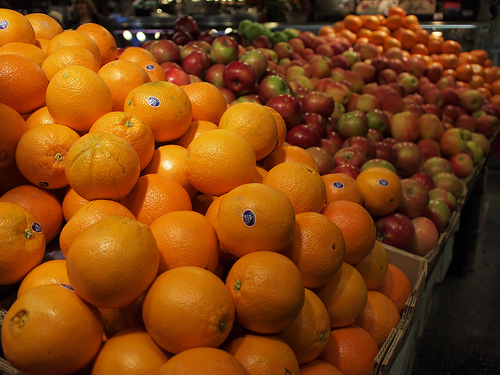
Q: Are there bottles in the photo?
A: No, there are no bottles.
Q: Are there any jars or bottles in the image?
A: No, there are no bottles or jars.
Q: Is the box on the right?
A: Yes, the box is on the right of the image.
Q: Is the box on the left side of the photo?
A: No, the box is on the right of the image.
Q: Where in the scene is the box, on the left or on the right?
A: The box is on the right of the image.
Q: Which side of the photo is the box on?
A: The box is on the right of the image.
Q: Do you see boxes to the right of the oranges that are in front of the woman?
A: Yes, there is a box to the right of the oranges.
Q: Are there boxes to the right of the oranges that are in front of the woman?
A: Yes, there is a box to the right of the oranges.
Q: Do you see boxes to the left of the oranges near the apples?
A: No, the box is to the right of the oranges.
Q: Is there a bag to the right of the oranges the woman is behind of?
A: No, there is a box to the right of the oranges.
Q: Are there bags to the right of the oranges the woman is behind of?
A: No, there is a box to the right of the oranges.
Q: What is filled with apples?
A: The box is filled with apples.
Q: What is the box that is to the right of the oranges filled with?
A: The box is filled with apples.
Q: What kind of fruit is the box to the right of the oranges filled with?
A: The box is filled with apples.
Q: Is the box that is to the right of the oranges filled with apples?
A: Yes, the box is filled with apples.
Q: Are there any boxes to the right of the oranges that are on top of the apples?
A: Yes, there is a box to the right of the oranges.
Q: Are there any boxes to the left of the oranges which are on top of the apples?
A: No, the box is to the right of the oranges.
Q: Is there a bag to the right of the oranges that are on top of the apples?
A: No, there is a box to the right of the oranges.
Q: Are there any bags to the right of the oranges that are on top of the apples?
A: No, there is a box to the right of the oranges.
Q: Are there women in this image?
A: Yes, there is a woman.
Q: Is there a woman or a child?
A: Yes, there is a woman.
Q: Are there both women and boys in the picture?
A: No, there is a woman but no boys.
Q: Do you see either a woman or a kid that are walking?
A: Yes, the woman is walking.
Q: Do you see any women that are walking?
A: Yes, there is a woman that is walking.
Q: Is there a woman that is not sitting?
A: Yes, there is a woman that is walking.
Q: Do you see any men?
A: No, there are no men.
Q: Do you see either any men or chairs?
A: No, there are no men or chairs.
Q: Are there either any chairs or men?
A: No, there are no men or chairs.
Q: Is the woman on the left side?
A: Yes, the woman is on the left of the image.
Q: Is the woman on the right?
A: No, the woman is on the left of the image.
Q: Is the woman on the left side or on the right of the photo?
A: The woman is on the left of the image.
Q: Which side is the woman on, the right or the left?
A: The woman is on the left of the image.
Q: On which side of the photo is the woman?
A: The woman is on the left of the image.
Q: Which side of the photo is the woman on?
A: The woman is on the left of the image.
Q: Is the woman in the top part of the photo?
A: Yes, the woman is in the top of the image.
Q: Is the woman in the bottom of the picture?
A: No, the woman is in the top of the image.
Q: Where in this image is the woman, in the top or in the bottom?
A: The woman is in the top of the image.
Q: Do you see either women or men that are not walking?
A: No, there is a woman but she is walking.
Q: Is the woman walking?
A: Yes, the woman is walking.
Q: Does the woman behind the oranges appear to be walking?
A: Yes, the woman is walking.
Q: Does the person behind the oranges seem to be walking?
A: Yes, the woman is walking.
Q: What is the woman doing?
A: The woman is walking.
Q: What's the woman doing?
A: The woman is walking.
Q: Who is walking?
A: The woman is walking.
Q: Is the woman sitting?
A: No, the woman is walking.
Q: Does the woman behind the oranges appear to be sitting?
A: No, the woman is walking.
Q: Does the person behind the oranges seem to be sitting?
A: No, the woman is walking.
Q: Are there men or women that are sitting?
A: No, there is a woman but she is walking.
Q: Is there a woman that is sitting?
A: No, there is a woman but she is walking.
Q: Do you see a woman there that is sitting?
A: No, there is a woman but she is walking.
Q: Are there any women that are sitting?
A: No, there is a woman but she is walking.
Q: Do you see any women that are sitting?
A: No, there is a woman but she is walking.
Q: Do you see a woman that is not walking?
A: No, there is a woman but she is walking.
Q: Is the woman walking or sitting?
A: The woman is walking.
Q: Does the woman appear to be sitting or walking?
A: The woman is walking.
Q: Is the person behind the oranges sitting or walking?
A: The woman is walking.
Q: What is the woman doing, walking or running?
A: The woman is walking.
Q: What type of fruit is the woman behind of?
A: The woman is behind the oranges.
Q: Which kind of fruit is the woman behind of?
A: The woman is behind the oranges.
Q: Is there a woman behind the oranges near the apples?
A: Yes, there is a woman behind the oranges.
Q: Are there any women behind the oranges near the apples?
A: Yes, there is a woman behind the oranges.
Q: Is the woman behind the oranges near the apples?
A: Yes, the woman is behind the oranges.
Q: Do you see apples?
A: Yes, there is an apple.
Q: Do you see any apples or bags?
A: Yes, there is an apple.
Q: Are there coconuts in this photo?
A: No, there are no coconuts.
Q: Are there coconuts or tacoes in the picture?
A: No, there are no coconuts or tacoes.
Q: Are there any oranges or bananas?
A: Yes, there are oranges.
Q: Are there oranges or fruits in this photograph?
A: Yes, there are oranges.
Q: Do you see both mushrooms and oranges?
A: No, there are oranges but no mushrooms.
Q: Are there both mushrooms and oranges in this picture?
A: No, there are oranges but no mushrooms.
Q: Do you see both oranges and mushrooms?
A: No, there are oranges but no mushrooms.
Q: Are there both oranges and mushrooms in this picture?
A: No, there are oranges but no mushrooms.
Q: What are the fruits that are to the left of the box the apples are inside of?
A: The fruits are oranges.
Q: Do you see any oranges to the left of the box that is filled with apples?
A: Yes, there are oranges to the left of the box.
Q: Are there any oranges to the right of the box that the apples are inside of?
A: No, the oranges are to the left of the box.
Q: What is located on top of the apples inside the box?
A: The oranges are on top of the apples.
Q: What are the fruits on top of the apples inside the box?
A: The fruits are oranges.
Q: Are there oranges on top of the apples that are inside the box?
A: Yes, there are oranges on top of the apples.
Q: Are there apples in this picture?
A: Yes, there are apples.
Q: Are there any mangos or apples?
A: Yes, there are apples.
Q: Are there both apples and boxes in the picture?
A: Yes, there are both apples and a box.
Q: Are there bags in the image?
A: No, there are no bags.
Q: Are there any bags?
A: No, there are no bags.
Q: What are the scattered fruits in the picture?
A: The fruits are apples.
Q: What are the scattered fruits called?
A: The fruits are apples.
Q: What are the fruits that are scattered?
A: The fruits are apples.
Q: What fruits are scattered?
A: The fruits are apples.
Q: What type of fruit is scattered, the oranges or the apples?
A: The apples are scattered.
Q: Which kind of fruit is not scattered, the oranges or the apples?
A: The oranges are not scattered.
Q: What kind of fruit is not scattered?
A: The fruit is oranges.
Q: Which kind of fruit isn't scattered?
A: The fruit is oranges.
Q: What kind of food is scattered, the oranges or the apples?
A: The apples is scattered.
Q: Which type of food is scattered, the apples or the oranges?
A: The apples is scattered.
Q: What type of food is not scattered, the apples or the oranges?
A: The oranges is not scattered.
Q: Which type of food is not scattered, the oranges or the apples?
A: The oranges is not scattered.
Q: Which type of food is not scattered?
A: The food is oranges.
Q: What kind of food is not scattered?
A: The food is oranges.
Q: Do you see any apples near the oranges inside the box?
A: Yes, there are apples near the oranges.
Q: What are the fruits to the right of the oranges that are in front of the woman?
A: The fruits are apples.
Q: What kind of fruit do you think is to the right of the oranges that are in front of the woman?
A: The fruits are apples.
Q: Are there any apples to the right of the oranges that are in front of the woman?
A: Yes, there are apples to the right of the oranges.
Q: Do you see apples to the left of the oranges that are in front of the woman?
A: No, the apples are to the right of the oranges.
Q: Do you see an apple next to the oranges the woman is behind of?
A: Yes, there are apples next to the oranges.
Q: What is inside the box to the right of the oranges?
A: The apples are inside the box.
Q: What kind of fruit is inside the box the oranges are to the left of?
A: The fruits are apples.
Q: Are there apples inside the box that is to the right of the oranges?
A: Yes, there are apples inside the box.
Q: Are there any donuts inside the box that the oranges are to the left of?
A: No, there are apples inside the box.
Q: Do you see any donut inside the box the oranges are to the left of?
A: No, there are apples inside the box.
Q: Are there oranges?
A: Yes, there are oranges.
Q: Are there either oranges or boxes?
A: Yes, there are oranges.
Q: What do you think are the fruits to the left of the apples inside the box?
A: The fruits are oranges.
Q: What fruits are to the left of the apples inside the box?
A: The fruits are oranges.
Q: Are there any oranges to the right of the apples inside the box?
A: No, the oranges are to the left of the apples.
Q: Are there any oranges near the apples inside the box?
A: Yes, there are oranges near the apples.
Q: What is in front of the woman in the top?
A: The oranges are in front of the woman.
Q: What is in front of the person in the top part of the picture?
A: The oranges are in front of the woman.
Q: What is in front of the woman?
A: The oranges are in front of the woman.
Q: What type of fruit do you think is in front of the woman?
A: The fruits are oranges.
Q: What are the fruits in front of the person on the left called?
A: The fruits are oranges.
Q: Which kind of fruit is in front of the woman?
A: The fruits are oranges.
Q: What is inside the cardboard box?
A: The oranges are inside the box.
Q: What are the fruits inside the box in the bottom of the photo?
A: The fruits are oranges.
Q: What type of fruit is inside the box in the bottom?
A: The fruits are oranges.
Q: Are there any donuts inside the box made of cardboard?
A: No, there are oranges inside the box.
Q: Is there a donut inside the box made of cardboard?
A: No, there are oranges inside the box.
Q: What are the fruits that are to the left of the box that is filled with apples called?
A: The fruits are oranges.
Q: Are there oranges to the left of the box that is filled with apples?
A: Yes, there are oranges to the left of the box.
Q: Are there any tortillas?
A: No, there are no tortillas.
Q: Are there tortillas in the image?
A: No, there are no tortillas.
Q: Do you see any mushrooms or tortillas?
A: No, there are no tortillas or mushrooms.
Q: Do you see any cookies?
A: No, there are no cookies.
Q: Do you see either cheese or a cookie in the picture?
A: No, there are no cookies or cheese.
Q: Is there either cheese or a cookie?
A: No, there are no cookies or cheese.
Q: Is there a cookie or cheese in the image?
A: No, there are no cookies or cheese.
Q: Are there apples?
A: Yes, there is an apple.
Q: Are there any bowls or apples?
A: Yes, there is an apple.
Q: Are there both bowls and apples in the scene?
A: No, there is an apple but no bowls.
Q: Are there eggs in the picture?
A: No, there are no eggs.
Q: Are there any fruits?
A: Yes, there is a fruit.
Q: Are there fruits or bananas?
A: Yes, there is a fruit.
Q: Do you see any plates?
A: No, there are no plates.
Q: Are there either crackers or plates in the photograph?
A: No, there are no plates or crackers.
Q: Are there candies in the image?
A: No, there are no candies.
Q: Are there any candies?
A: No, there are no candies.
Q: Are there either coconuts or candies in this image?
A: No, there are no candies or coconuts.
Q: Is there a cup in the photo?
A: No, there are no cups.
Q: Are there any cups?
A: No, there are no cups.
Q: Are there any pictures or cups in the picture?
A: No, there are no cups or pictures.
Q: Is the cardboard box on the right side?
A: Yes, the box is on the right of the image.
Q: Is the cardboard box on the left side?
A: No, the box is on the right of the image.